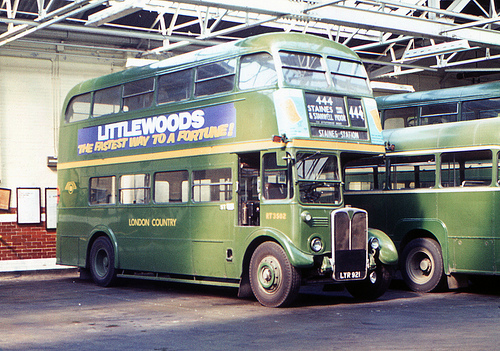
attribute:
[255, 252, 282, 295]
hubcap — green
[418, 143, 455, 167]
ground — green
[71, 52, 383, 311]
bus — old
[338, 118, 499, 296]
bus — green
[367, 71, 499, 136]
bus — green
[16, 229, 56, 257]
brick — red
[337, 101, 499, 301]
bus — parked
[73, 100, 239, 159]
ad — blue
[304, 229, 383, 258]
headlights — white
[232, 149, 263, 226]
window — tall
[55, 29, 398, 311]
bus — green, parked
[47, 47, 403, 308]
bus — big